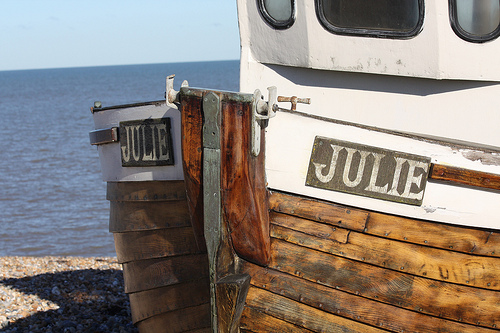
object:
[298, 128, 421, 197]
name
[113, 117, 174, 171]
name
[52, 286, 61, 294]
rocks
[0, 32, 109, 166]
sea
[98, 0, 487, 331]
boat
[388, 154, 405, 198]
letter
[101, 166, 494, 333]
wood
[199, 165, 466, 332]
boat base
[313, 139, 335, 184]
letter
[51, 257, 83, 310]
ground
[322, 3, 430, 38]
windows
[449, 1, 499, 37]
windows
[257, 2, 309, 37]
windows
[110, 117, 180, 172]
boats name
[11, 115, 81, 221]
water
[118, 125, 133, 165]
letter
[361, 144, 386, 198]
letter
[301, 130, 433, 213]
sign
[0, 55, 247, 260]
lake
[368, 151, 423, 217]
letter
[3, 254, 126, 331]
beach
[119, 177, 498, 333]
bottom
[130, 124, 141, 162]
letter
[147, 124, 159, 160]
letter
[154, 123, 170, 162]
letter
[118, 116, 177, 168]
sign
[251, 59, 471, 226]
side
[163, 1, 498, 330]
front end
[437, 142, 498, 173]
paint